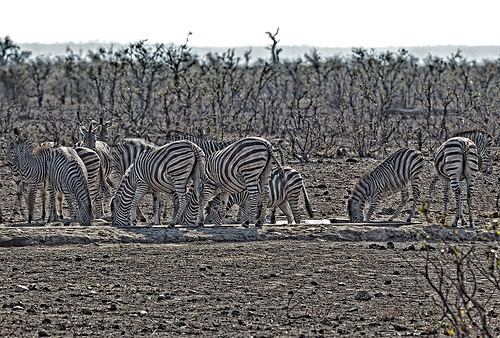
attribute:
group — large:
[13, 120, 485, 242]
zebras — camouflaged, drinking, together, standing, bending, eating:
[13, 128, 323, 220]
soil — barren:
[123, 241, 336, 312]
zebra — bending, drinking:
[342, 139, 427, 236]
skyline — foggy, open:
[257, 0, 379, 49]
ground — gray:
[166, 259, 423, 320]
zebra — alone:
[432, 124, 498, 228]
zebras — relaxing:
[339, 122, 500, 226]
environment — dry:
[6, 36, 500, 333]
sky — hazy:
[86, 1, 421, 35]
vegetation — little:
[3, 29, 499, 136]